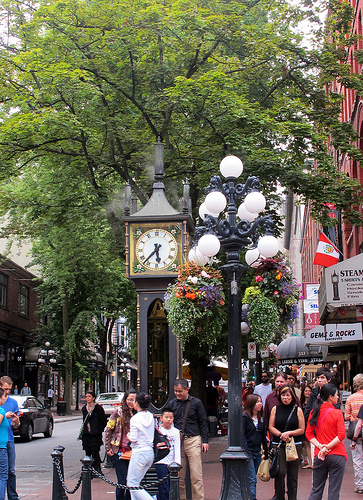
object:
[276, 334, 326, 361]
awning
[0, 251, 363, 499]
commercial area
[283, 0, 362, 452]
building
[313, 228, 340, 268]
flag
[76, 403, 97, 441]
bag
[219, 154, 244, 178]
globe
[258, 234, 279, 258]
globe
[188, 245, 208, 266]
globe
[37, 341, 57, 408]
lamppost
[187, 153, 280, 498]
lamppost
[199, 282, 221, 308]
flower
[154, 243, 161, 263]
hand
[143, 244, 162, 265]
hand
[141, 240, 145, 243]
numerals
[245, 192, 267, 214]
globe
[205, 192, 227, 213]
globe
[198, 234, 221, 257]
globe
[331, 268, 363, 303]
sign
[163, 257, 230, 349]
plants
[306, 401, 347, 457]
shirt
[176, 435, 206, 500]
pants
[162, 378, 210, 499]
man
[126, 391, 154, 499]
person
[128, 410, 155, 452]
jacket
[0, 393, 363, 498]
ground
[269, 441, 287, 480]
brown bag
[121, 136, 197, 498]
tower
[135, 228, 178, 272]
clock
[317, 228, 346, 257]
pole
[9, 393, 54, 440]
black car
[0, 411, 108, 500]
road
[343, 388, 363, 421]
shirt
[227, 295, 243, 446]
pole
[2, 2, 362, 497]
downtown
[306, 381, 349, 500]
woman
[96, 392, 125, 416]
car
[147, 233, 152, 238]
numeral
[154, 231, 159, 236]
numeral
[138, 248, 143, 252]
numerals